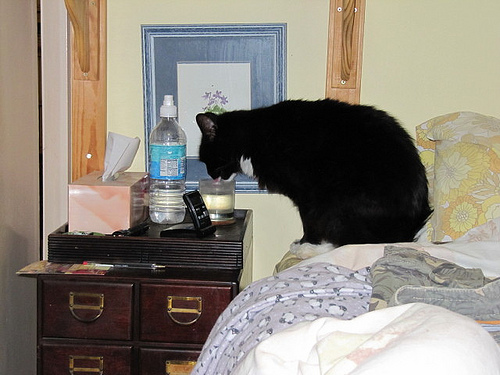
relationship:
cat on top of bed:
[195, 101, 434, 245] [290, 257, 499, 374]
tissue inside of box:
[96, 127, 146, 191] [63, 173, 150, 237]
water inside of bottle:
[153, 188, 189, 217] [150, 91, 188, 234]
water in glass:
[201, 192, 236, 208] [199, 178, 237, 221]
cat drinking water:
[195, 101, 434, 245] [201, 192, 236, 208]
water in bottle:
[153, 188, 189, 217] [150, 91, 188, 234]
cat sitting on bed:
[195, 101, 434, 245] [290, 257, 499, 374]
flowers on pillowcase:
[455, 132, 500, 189] [416, 112, 499, 241]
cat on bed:
[195, 101, 434, 245] [290, 257, 499, 374]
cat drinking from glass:
[195, 101, 434, 245] [199, 178, 237, 221]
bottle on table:
[150, 91, 188, 234] [34, 267, 240, 372]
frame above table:
[140, 24, 285, 104] [34, 267, 240, 372]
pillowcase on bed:
[416, 112, 499, 241] [290, 257, 499, 374]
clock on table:
[179, 188, 217, 234] [34, 267, 240, 372]